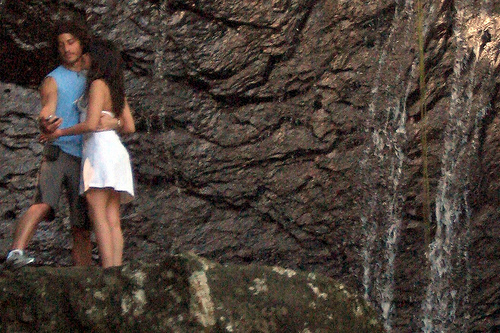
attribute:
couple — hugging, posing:
[5, 24, 137, 266]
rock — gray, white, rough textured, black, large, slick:
[1, 254, 381, 330]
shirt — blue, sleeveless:
[48, 64, 85, 157]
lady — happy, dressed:
[37, 39, 135, 266]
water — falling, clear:
[354, 4, 499, 330]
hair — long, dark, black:
[81, 36, 128, 116]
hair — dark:
[55, 25, 88, 51]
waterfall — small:
[354, 1, 499, 332]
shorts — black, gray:
[35, 146, 88, 227]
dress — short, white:
[76, 96, 136, 208]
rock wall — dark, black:
[1, 1, 496, 332]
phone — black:
[44, 114, 60, 123]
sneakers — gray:
[5, 250, 38, 265]